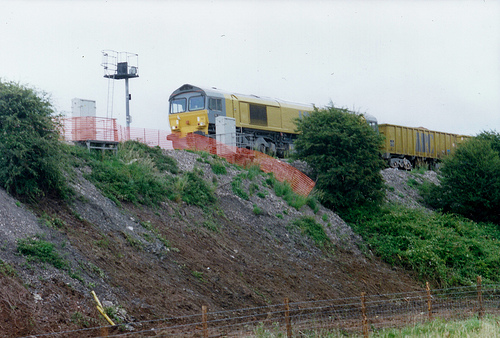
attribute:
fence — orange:
[170, 134, 300, 194]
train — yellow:
[157, 70, 495, 184]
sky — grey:
[237, 34, 355, 94]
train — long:
[136, 65, 468, 194]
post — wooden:
[357, 283, 373, 335]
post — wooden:
[420, 269, 483, 329]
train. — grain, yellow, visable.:
[168, 82, 476, 174]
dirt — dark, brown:
[0, 150, 497, 337]